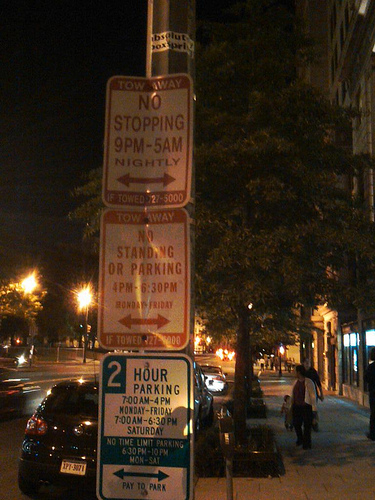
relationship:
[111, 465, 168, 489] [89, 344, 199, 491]
arrow on sign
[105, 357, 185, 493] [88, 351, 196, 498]
words on sign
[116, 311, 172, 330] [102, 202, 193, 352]
arrows on sign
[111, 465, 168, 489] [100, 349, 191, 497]
arrow on signs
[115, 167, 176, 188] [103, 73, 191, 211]
arrows on sign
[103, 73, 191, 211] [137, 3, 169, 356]
sign on pole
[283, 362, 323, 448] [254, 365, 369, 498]
lady walking on sidewalk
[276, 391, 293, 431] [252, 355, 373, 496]
kid walking on sidewalk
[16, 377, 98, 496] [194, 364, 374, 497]
car parked beside sidewalk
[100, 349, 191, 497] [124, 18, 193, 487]
signs on pole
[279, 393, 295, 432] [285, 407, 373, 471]
boy on street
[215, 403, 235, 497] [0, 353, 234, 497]
parking meter beside road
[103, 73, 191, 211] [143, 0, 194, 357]
sign on pole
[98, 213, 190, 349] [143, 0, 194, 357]
sign on pole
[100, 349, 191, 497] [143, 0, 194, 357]
signs on pole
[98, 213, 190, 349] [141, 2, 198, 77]
sign on pole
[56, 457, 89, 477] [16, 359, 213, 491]
license plate on car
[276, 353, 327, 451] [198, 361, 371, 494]
family walking on street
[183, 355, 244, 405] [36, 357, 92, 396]
car parked on road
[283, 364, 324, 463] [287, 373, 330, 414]
woman wearing jacket